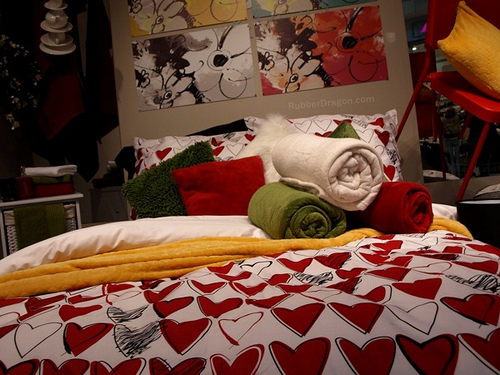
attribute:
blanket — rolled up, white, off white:
[271, 125, 379, 211]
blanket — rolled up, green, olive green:
[237, 176, 347, 235]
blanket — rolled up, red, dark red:
[365, 177, 429, 234]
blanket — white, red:
[8, 211, 500, 374]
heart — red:
[277, 303, 324, 333]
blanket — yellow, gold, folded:
[10, 223, 375, 285]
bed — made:
[1, 134, 499, 373]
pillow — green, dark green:
[121, 141, 216, 220]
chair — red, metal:
[396, 3, 500, 199]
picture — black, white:
[127, 3, 389, 83]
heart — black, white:
[216, 314, 259, 340]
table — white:
[4, 193, 79, 230]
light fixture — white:
[39, 5, 77, 50]